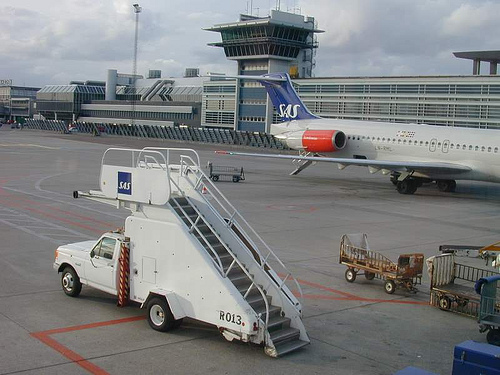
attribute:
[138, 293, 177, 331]
wheel — black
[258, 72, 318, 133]
crate — white, blue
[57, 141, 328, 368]
truck — white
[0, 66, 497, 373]
air port — large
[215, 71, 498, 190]
airplane — blue 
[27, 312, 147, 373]
painted concrete — Small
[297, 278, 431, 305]
painted concrete — Small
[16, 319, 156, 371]
concrete — painted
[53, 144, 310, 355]
truck — blue 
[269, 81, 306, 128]
letters — white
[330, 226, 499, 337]
trolley — luggage holder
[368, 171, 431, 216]
wheel — black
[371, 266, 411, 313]
wheel — black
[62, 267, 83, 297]
wheel — front wheel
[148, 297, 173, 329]
wheel — back wheel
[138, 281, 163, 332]
wheel — black